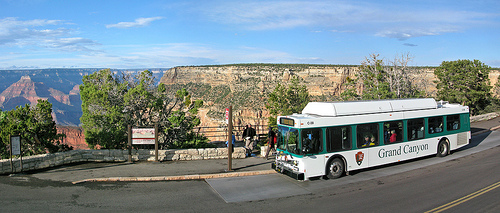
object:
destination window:
[278, 116, 296, 129]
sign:
[8, 132, 24, 173]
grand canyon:
[1, 63, 482, 146]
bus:
[269, 96, 471, 181]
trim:
[272, 110, 471, 158]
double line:
[419, 180, 485, 209]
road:
[0, 124, 483, 211]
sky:
[0, 0, 499, 71]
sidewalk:
[0, 152, 278, 184]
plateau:
[155, 63, 498, 142]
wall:
[0, 147, 243, 175]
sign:
[127, 121, 160, 162]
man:
[264, 125, 277, 156]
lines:
[442, 175, 487, 203]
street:
[404, 179, 440, 194]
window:
[264, 109, 302, 135]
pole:
[226, 105, 236, 171]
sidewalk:
[197, 154, 230, 174]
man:
[240, 122, 257, 157]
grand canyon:
[137, 73, 225, 171]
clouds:
[105, 15, 166, 28]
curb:
[94, 170, 266, 189]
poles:
[7, 154, 17, 172]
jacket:
[239, 125, 254, 140]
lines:
[437, 183, 479, 211]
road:
[364, 169, 438, 189]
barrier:
[177, 110, 256, 165]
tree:
[433, 55, 497, 114]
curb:
[107, 165, 218, 186]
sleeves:
[265, 120, 284, 161]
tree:
[79, 67, 204, 149]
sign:
[130, 127, 156, 144]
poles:
[126, 125, 135, 163]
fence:
[156, 128, 265, 143]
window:
[349, 120, 383, 147]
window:
[445, 111, 465, 137]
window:
[407, 120, 427, 141]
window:
[384, 120, 402, 147]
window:
[355, 121, 380, 145]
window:
[326, 127, 354, 152]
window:
[300, 128, 322, 154]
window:
[277, 126, 302, 157]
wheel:
[327, 159, 346, 180]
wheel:
[435, 140, 449, 156]